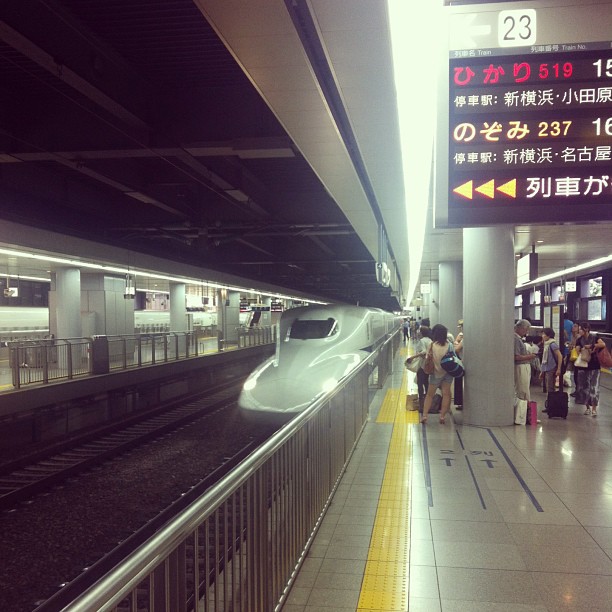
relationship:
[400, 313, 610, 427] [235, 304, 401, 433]
people are waiting for train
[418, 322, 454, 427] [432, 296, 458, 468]
person standing up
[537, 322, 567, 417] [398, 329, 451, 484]
person standing up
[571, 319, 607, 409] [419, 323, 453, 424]
person standing person